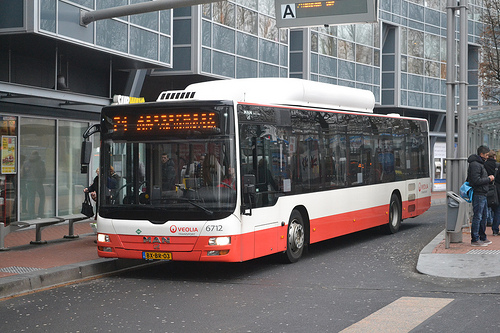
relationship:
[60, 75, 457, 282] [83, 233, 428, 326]
bus on street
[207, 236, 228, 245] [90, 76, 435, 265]
headlight of bus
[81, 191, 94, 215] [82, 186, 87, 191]
black purse in persons hand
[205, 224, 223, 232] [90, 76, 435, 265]
number on bus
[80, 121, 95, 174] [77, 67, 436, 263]
side mirror of vehicle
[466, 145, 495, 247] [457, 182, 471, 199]
man with bag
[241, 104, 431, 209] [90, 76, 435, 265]
window of bus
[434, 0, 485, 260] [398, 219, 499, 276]
post in sidewalk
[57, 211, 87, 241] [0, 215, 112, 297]
bench on sidewalk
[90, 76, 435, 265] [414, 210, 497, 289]
bus at sidewalk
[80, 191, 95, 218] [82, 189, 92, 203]
black purse with handles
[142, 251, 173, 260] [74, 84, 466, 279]
license plate on bus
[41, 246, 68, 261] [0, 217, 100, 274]
brick on sidewalk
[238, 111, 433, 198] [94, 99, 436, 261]
windows on bus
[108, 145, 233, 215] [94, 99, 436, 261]
windows on bus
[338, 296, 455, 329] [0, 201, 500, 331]
line on street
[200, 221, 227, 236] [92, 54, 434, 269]
number on bus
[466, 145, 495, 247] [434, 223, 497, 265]
man on sidewalk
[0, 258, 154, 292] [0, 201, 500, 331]
curb next to street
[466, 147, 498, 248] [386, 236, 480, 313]
man standing in sidewalk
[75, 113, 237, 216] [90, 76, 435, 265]
windshield on bus